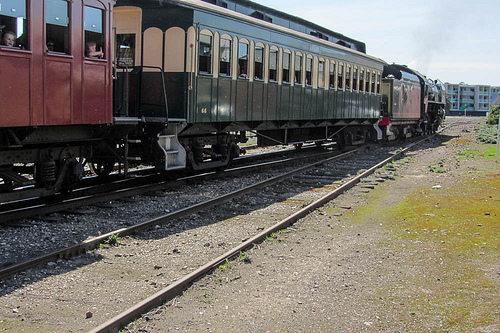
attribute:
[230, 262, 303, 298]
ground — asphalt, green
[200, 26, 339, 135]
train — red, green, greeny, passenger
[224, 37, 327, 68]
windows — closed, rectangular, here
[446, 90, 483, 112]
building — white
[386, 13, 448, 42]
sky — blue, thisy, clear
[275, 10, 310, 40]
rails — these, here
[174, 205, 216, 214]
gravel — gray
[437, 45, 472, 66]
clouds — white